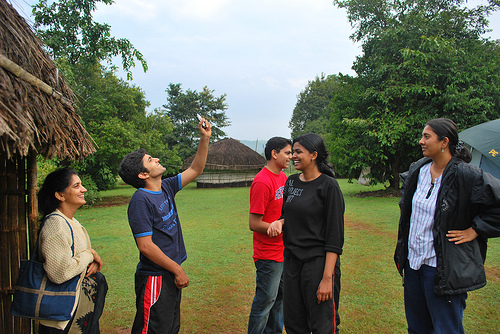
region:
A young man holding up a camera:
[118, 114, 213, 332]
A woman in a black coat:
[395, 117, 499, 330]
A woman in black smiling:
[267, 135, 343, 332]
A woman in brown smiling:
[13, 165, 107, 332]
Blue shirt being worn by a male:
[123, 171, 188, 271]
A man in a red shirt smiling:
[248, 135, 292, 331]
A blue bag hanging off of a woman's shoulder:
[11, 210, 81, 322]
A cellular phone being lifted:
[192, 111, 212, 133]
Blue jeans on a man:
[246, 258, 284, 333]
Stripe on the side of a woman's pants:
[331, 268, 338, 332]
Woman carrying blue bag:
[10, 165, 110, 332]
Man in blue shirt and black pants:
[111, 107, 214, 332]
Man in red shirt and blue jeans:
[243, 134, 299, 332]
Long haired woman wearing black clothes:
[267, 135, 343, 332]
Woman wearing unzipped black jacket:
[390, 117, 497, 332]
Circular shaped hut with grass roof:
[177, 136, 274, 188]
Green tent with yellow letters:
[441, 115, 499, 188]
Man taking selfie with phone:
[116, 108, 215, 333]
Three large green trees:
[25, 1, 231, 203]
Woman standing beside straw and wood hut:
[3, 5, 112, 332]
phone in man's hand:
[186, 102, 222, 138]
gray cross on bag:
[6, 268, 70, 308]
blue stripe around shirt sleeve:
[112, 221, 164, 243]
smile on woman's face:
[287, 155, 307, 168]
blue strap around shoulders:
[31, 204, 85, 254]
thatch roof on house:
[223, 144, 250, 166]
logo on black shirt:
[282, 183, 319, 205]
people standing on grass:
[63, 104, 477, 299]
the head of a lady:
[420, 116, 455, 158]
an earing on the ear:
[442, 145, 446, 155]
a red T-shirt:
[254, 173, 274, 204]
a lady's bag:
[16, 261, 73, 316]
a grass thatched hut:
[221, 135, 257, 165]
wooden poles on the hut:
[0, 168, 35, 325]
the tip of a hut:
[216, 130, 234, 146]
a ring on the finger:
[459, 233, 464, 240]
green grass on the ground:
[195, 190, 248, 270]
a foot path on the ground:
[344, 207, 397, 244]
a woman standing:
[389, 115, 498, 332]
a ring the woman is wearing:
[458, 233, 465, 239]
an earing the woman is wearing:
[438, 145, 445, 152]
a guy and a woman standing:
[242, 131, 349, 331]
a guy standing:
[115, 110, 216, 331]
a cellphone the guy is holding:
[193, 110, 208, 130]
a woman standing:
[6, 163, 109, 331]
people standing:
[8, 108, 499, 333]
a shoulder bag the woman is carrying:
[5, 211, 91, 322]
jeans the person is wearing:
[246, 259, 283, 332]